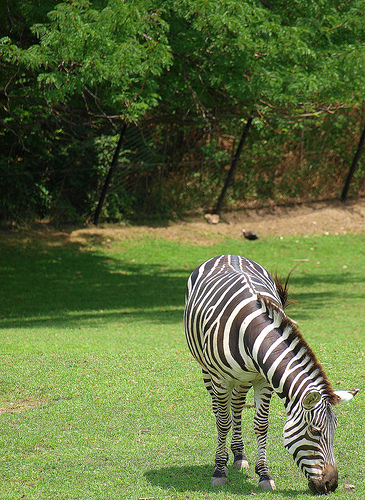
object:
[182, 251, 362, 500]
zebra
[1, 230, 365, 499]
grass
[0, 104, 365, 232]
fence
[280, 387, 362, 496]
head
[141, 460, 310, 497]
shadow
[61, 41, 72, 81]
trees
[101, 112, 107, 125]
branches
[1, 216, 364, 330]
shade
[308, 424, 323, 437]
eye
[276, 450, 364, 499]
grazing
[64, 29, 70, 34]
green leaves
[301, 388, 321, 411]
ears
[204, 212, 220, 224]
rocks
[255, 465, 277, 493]
hooves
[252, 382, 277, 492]
legs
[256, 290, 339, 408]
mane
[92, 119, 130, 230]
posts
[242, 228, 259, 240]
rock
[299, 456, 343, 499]
graze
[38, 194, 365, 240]
dirt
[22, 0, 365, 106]
sun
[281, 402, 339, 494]
face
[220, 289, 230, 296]
stripes